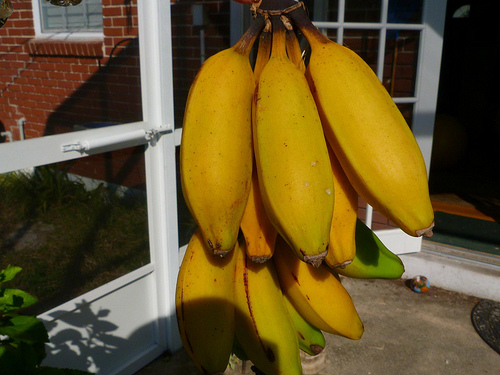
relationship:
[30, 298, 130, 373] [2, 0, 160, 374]
shadow on door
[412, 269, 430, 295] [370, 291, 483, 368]
toy on ground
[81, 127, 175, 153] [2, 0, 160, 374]
spring on door